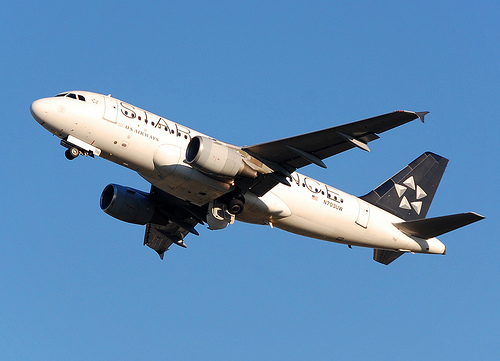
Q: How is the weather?
A: It is clear.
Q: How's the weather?
A: It is clear.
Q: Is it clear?
A: Yes, it is clear.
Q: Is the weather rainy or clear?
A: It is clear.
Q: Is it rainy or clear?
A: It is clear.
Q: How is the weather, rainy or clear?
A: It is clear.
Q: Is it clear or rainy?
A: It is clear.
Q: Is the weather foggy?
A: No, it is clear.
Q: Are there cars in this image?
A: No, there are no cars.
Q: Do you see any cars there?
A: No, there are no cars.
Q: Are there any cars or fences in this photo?
A: No, there are no cars or fences.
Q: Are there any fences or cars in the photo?
A: No, there are no cars or fences.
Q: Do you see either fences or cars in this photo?
A: No, there are no cars or fences.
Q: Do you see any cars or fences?
A: No, there are no cars or fences.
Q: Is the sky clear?
A: Yes, the sky is clear.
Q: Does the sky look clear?
A: Yes, the sky is clear.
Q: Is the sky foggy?
A: No, the sky is clear.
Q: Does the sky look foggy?
A: No, the sky is clear.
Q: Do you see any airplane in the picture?
A: Yes, there is an airplane.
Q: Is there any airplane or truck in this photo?
A: Yes, there is an airplane.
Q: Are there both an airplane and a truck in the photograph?
A: No, there is an airplane but no trucks.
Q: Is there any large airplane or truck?
A: Yes, there is a large airplane.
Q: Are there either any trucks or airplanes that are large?
A: Yes, the airplane is large.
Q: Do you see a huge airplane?
A: Yes, there is a huge airplane.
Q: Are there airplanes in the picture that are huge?
A: Yes, there is an airplane that is huge.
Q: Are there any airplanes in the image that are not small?
A: Yes, there is a huge airplane.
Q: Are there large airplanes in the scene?
A: Yes, there is a large airplane.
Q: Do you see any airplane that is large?
A: Yes, there is a large airplane.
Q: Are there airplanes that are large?
A: Yes, there is an airplane that is large.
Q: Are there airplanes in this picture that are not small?
A: Yes, there is a large airplane.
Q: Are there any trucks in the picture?
A: No, there are no trucks.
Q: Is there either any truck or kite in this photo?
A: No, there are no trucks or kites.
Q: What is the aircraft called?
A: The aircraft is an airplane.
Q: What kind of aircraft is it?
A: The aircraft is an airplane.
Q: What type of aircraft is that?
A: This is an airplane.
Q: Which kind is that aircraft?
A: This is an airplane.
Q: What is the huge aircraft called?
A: The aircraft is an airplane.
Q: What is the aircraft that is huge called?
A: The aircraft is an airplane.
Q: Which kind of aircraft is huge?
A: The aircraft is an airplane.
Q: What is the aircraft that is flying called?
A: The aircraft is an airplane.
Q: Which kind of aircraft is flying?
A: The aircraft is an airplane.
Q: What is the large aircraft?
A: The aircraft is an airplane.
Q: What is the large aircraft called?
A: The aircraft is an airplane.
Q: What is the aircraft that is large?
A: The aircraft is an airplane.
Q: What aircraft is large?
A: The aircraft is an airplane.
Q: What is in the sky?
A: The plane is in the sky.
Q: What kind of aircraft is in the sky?
A: The aircraft is an airplane.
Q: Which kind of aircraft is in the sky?
A: The aircraft is an airplane.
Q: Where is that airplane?
A: The airplane is in the sky.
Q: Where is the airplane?
A: The airplane is in the sky.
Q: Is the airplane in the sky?
A: Yes, the airplane is in the sky.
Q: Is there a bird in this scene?
A: No, there are no birds.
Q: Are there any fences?
A: No, there are no fences.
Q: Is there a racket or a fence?
A: No, there are no fences or rackets.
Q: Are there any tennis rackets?
A: No, there are no tennis rackets.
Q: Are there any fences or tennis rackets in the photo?
A: No, there are no tennis rackets or fences.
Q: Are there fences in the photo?
A: No, there are no fences.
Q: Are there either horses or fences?
A: No, there are no fences or horses.